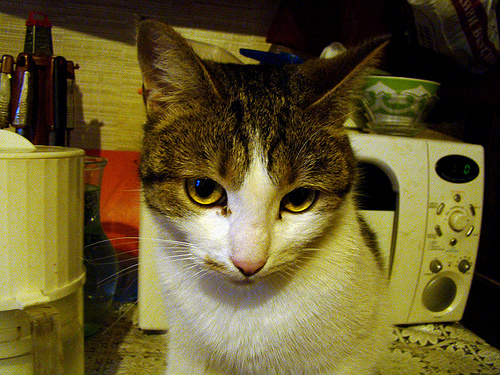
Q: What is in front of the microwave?
A: A cat.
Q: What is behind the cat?
A: A microwave.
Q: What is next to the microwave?
A: A blue vase.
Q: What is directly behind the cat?
A: Microwave.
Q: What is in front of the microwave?
A: A cat.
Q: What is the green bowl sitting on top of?
A: Microwave.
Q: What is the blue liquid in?
A: A vase.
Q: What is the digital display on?
A: The microwave.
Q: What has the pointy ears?
A: The cat.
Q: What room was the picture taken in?
A: The kitchen.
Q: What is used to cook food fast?
A: The microwave.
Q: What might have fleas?
A: The cat.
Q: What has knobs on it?
A: The microwave.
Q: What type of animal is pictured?
A: A cat.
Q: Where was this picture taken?
A: In a kitchen.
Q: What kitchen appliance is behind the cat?
A: A microwave.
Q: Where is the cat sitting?
A: On a counter.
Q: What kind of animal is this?
A: Cat.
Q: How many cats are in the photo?
A: One.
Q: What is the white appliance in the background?
A: Microwave.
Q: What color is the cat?
A: Grey and white.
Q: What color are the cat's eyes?
A: Yellow and black.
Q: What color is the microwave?
A: White and silver.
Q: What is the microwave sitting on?
A: White doily cloth.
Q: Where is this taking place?
A: Kitchen counter.